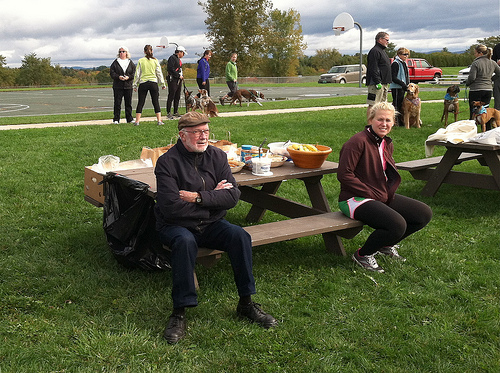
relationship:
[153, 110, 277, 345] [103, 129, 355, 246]
man sitting at picnic table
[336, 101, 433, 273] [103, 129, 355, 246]
woman sitting at picnic table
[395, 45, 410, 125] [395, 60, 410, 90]
woman wearing vest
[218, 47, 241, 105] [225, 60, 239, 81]
person wearing jacket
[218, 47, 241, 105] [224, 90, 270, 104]
person walking dog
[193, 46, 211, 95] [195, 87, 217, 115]
man walking dog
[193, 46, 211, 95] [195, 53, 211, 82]
man wearing blue shirt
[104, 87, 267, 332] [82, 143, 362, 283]
gentleman sitting on bench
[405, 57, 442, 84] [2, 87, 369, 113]
truck in parking lot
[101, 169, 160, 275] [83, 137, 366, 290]
garbage bag in picnic table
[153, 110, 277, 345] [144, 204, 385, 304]
man sitting on bench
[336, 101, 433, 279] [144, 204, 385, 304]
woman sitting on bench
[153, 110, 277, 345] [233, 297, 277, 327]
man has foot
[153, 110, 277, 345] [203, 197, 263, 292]
man has knee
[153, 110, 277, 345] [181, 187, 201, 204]
man has hand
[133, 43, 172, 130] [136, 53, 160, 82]
woman wearing yellow shirt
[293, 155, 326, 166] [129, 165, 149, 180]
bowl on table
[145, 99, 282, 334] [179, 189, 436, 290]
man on bench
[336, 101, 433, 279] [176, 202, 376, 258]
woman sitting on bench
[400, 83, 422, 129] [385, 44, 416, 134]
dog standing by owner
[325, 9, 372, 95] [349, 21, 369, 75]
basketball goa on pole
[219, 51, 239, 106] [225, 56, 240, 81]
person wearing jacket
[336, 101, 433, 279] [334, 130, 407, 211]
woman wears jacket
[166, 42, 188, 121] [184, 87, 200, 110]
man with dog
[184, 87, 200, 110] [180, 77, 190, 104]
dog on leash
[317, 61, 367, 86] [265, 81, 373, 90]
car in parking lot